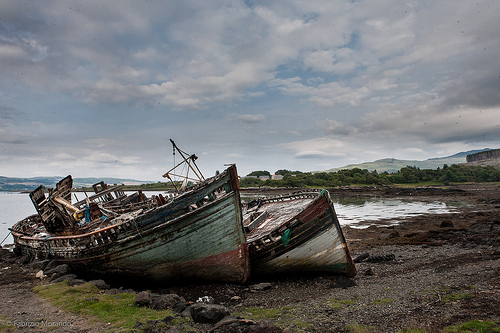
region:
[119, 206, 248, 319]
a ship wreckage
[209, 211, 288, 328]
a ship wreckage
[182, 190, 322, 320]
a ship wreckage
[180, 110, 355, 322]
a ship wreckage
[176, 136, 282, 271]
a ship wreckage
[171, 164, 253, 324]
a ship wreckage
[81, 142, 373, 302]
old boats on sea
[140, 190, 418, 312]
old boats on sea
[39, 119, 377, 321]
old boats on bay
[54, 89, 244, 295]
old boats on bay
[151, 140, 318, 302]
old boats on bay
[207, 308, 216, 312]
the rock is black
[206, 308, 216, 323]
the rock is black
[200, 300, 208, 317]
the rock is black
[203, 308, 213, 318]
the rock is black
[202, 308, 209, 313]
the rock is black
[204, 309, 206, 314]
the rock is black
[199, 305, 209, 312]
the rock is black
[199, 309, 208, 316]
the rock is black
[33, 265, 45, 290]
white mark is spotted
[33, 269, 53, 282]
white mark is spotted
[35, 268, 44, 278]
white mark is spotted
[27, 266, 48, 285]
white mark is spotted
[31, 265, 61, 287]
white mark is spotted